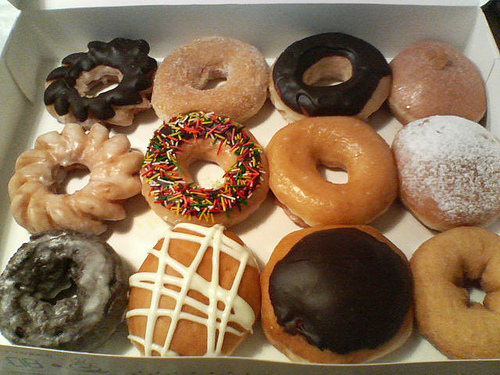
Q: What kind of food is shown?
A: Donut.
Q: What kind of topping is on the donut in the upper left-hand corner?
A: Chocolate.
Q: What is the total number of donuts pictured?
A: 12.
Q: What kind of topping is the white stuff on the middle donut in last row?
A: Powdered sugar.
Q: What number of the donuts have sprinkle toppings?
A: 1.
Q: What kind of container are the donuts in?
A: Cardboard box.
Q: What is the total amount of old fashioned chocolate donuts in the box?
A: 1.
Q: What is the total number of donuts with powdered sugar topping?
A: 1.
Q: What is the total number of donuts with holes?
A: 8.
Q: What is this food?
A: Donuts.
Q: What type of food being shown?
A: Donuts.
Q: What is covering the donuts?
A: Icing and sprinkles.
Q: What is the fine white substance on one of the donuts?
A: Sugar.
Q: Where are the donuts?
A: In a box.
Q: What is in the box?
A: A dozen donuts.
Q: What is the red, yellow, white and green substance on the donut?
A: Sprinkles.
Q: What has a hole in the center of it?
A: A donut.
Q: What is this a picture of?
A: A box of donuts.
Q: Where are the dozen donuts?
A: In a box.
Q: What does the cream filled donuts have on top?
A: Chocolate glaze.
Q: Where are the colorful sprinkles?
A: On the doughnut.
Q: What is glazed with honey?
A: A doughnut.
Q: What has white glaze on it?
A: A doughnut.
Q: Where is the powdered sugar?
A: On the doughnut.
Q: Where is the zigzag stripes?
A: On the the donut.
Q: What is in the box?
A: Doughnuts.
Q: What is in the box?
A: Donuts.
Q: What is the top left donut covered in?
A: Chocolate.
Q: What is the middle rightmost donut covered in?
A: Powdered sugar.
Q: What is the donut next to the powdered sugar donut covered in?
A: Glaze.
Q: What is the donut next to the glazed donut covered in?
A: Sprinkles.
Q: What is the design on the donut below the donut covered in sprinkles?
A: Cross hatched.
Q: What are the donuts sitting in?
A: A white cardboard box.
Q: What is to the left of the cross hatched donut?
A: A chocolate donut covered in glaze.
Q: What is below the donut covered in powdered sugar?
A: A plain unglazed donut.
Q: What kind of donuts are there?
A: Assorted.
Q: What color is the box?
A: White.